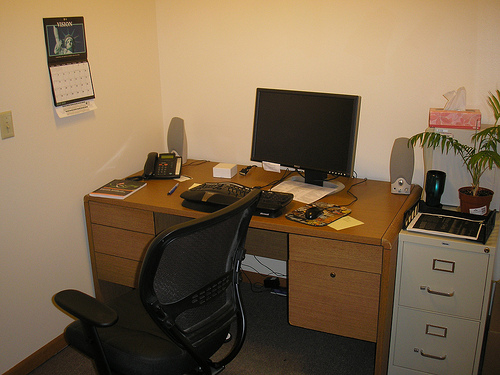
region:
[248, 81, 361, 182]
the monitor on the desk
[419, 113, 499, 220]
the plant on the filing cabinet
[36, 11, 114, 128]
the calendar on the wall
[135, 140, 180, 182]
the phone on the desk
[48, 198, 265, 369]
the chair is ergonomic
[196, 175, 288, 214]
the keyboard on the desk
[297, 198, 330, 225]
the mouse on the mousepad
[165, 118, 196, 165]
the speaker on the desk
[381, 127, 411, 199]
speaker on the desk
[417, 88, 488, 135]
the box of tissues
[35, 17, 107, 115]
A mothly calender hanging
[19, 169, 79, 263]
A smooth white wall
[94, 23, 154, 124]
A smooth white wall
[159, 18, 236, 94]
A smooth white wall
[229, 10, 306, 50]
A smooth white wall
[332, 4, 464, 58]
A smooth white wall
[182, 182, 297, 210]
A black computer keyboard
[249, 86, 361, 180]
a black computer monitor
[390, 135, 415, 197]
a gray speaker on a desk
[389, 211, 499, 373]
a gray metallic filling cabinet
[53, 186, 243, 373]
a black swiveling chair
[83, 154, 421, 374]
a wooden desk in an office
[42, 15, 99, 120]
a calendar on a wall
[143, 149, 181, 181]
a landline phone on a desk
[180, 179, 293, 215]
a black keyboard on a desk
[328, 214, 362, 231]
a yellow post-it note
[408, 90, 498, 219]
a green plant in a brown pot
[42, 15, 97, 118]
the calendar on the wall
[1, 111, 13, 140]
the switch plate on the wall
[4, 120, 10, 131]
the light switch on the wall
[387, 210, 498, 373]
the file cabinet next to the wall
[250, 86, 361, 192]
the monitor on the desk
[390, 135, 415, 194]
the speaker on the desk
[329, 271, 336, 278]
the lock on the desk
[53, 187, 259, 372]
the empty chair in front of the desk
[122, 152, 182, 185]
the phone on the desk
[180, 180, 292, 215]
the keyboard on the desk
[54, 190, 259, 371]
Black chair by the desk.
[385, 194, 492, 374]
Filing cabinet by the desk.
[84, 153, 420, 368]
Brown desk against the wall.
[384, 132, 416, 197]
Speaker on the desk.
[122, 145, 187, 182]
Telephone on the desk.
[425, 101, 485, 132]
box of tissues.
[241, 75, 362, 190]
Monitor on the desk.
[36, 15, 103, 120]
Calendar on the wall.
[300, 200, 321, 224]
mouse on the desk.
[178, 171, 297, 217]
Keyboard on the desk.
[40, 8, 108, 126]
A calender hanging on the wall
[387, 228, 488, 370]
A beige filing cabinet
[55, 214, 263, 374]
A black desk chair with armrests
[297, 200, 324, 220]
A black computer mouse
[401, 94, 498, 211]
A small potted plant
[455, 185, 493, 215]
A brown flower pot.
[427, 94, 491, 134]
A box of tissues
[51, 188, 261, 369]
black office chair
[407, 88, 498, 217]
plant with green leaves in a terra cotta pot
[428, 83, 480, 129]
pink and white box of tissue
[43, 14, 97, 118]
calendar with a picture of the statue of liberty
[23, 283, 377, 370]
dark brown carpeting under the desk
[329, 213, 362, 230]
yellow paper near a mouse pad